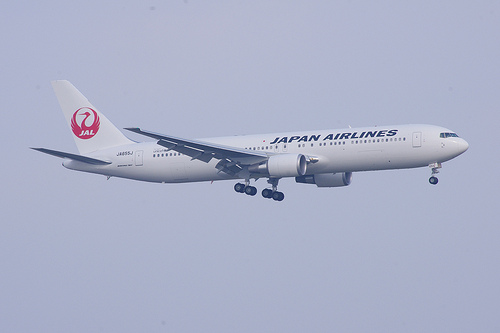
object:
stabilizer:
[24, 143, 109, 166]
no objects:
[13, 199, 498, 319]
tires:
[273, 190, 286, 201]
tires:
[261, 188, 276, 198]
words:
[271, 134, 321, 144]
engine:
[305, 170, 350, 189]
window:
[439, 132, 448, 138]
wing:
[121, 127, 322, 180]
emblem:
[67, 106, 102, 140]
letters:
[78, 130, 84, 136]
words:
[323, 129, 399, 140]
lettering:
[270, 137, 279, 143]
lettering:
[278, 137, 289, 143]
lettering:
[288, 136, 300, 143]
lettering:
[298, 135, 308, 142]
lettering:
[309, 134, 320, 141]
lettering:
[323, 134, 333, 141]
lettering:
[334, 133, 341, 140]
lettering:
[339, 133, 351, 140]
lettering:
[351, 132, 358, 139]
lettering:
[359, 131, 366, 139]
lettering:
[365, 131, 377, 137]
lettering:
[376, 129, 386, 137]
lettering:
[386, 130, 398, 137]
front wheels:
[427, 174, 440, 186]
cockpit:
[432, 123, 468, 164]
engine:
[261, 152, 312, 181]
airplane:
[28, 78, 470, 202]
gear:
[207, 152, 320, 206]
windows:
[385, 138, 389, 142]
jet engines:
[295, 168, 353, 188]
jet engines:
[247, 150, 307, 177]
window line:
[403, 137, 407, 142]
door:
[134, 145, 143, 169]